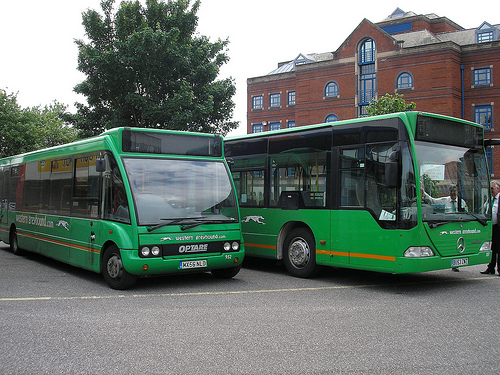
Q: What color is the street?
A: Gray.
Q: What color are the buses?
A: Green.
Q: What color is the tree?
A: Green.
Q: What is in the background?
A: A tree.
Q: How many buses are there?
A: Two.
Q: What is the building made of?
A: Brick.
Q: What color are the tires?
A: Black.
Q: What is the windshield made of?
A: Glass.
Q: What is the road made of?
A: Asphalt.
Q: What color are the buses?
A: Green.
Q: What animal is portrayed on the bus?
A: Greyhound.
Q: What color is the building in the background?
A: Red.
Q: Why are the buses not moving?
A: They are parked.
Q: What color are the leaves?
A: Green.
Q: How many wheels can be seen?
A: Three.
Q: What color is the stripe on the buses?
A: Orange.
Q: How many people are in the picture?
A: Two.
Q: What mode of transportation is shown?
A: Buses.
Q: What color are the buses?
A: Green.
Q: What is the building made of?
A: Brick.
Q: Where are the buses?
A: On the pavement.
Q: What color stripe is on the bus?
A: Orange.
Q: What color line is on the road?
A: White.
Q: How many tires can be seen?
A: 3.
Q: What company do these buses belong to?
A: Greyhound.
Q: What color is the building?
A: Brown.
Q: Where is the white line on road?
A: Front of 1st bus.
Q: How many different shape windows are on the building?
A: 3.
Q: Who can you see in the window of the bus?
A: Man white shirt.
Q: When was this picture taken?
A: Daytime.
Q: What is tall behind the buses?
A: Tree.